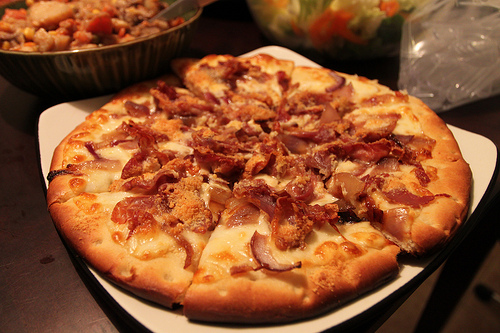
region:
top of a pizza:
[283, 149, 370, 213]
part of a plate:
[115, 302, 151, 317]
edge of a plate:
[104, 290, 120, 305]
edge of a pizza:
[146, 287, 182, 314]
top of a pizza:
[195, 155, 278, 248]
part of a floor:
[418, 285, 444, 316]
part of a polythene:
[396, 28, 442, 91]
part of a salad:
[326, 5, 370, 43]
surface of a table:
[35, 262, 89, 302]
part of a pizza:
[221, 84, 311, 186]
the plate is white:
[42, 107, 82, 144]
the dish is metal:
[37, 32, 190, 83]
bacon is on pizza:
[210, 122, 353, 227]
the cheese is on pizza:
[209, 226, 256, 269]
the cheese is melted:
[215, 233, 247, 270]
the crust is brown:
[190, 280, 328, 330]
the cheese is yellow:
[219, 230, 256, 262]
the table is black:
[1, 155, 79, 329]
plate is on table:
[2, 86, 253, 331]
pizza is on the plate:
[25, 75, 497, 324]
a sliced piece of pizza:
[202, 137, 385, 321]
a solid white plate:
[33, 47, 498, 331]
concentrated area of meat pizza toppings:
[170, 100, 320, 210]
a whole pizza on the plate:
[20, 40, 495, 325]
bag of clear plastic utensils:
[402, 3, 498, 98]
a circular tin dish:
[0, 11, 200, 76]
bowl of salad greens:
[250, 1, 399, 43]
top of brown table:
[8, 232, 64, 329]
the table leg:
[407, 224, 499, 329]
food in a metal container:
[0, 0, 200, 80]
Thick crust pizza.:
[31, 45, 481, 320]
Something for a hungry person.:
[34, 45, 486, 325]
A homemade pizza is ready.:
[40, 48, 476, 326]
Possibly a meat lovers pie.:
[35, 42, 487, 325]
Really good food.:
[39, 42, 478, 320]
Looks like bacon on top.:
[42, 48, 479, 321]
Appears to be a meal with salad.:
[233, 1, 464, 90]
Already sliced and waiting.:
[38, 46, 480, 326]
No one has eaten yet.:
[32, 40, 482, 326]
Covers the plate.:
[31, 45, 478, 325]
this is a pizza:
[51, 100, 421, 286]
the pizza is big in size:
[78, 99, 435, 253]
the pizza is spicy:
[141, 102, 388, 215]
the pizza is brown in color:
[67, 190, 100, 220]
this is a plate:
[477, 139, 491, 168]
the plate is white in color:
[478, 145, 489, 170]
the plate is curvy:
[51, 101, 75, 128]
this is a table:
[7, 249, 56, 321]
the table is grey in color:
[29, 256, 69, 331]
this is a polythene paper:
[426, 10, 493, 87]